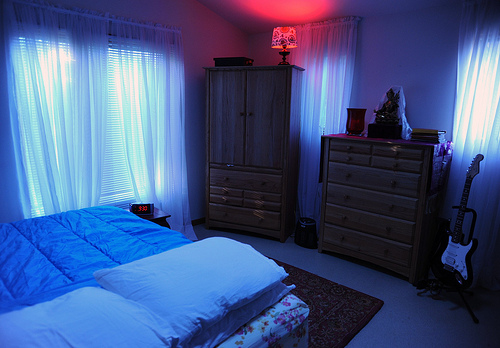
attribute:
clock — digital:
[129, 200, 158, 213]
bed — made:
[1, 200, 313, 347]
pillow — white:
[0, 284, 181, 343]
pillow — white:
[91, 233, 296, 327]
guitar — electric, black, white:
[433, 152, 490, 287]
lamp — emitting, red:
[268, 22, 301, 67]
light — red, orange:
[238, 2, 339, 27]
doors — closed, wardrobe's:
[211, 67, 286, 169]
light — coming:
[19, 38, 499, 214]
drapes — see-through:
[9, 5, 499, 242]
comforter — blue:
[3, 200, 196, 311]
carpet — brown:
[185, 223, 500, 341]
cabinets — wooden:
[188, 54, 455, 288]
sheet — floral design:
[224, 295, 317, 346]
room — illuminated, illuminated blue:
[2, 0, 500, 342]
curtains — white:
[0, 1, 201, 243]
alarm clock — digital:
[125, 199, 154, 216]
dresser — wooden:
[319, 125, 448, 288]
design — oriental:
[276, 257, 378, 340]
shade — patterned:
[272, 26, 299, 47]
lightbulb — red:
[281, 43, 289, 48]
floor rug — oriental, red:
[275, 254, 384, 345]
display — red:
[136, 203, 150, 213]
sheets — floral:
[221, 293, 311, 347]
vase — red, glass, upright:
[344, 104, 370, 139]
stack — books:
[409, 127, 451, 146]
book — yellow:
[412, 127, 449, 133]